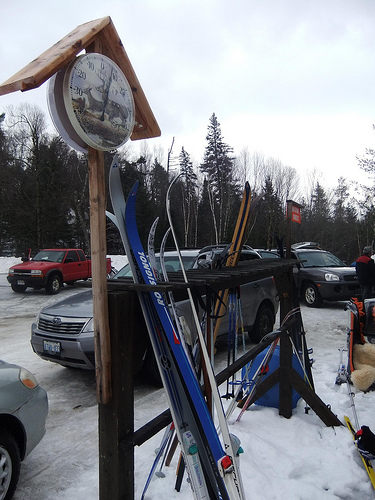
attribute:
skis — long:
[105, 155, 255, 499]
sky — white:
[1, 0, 375, 217]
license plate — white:
[43, 339, 64, 353]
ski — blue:
[124, 178, 224, 465]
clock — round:
[48, 51, 136, 153]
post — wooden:
[85, 153, 117, 407]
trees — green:
[1, 109, 372, 255]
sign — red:
[288, 205, 300, 224]